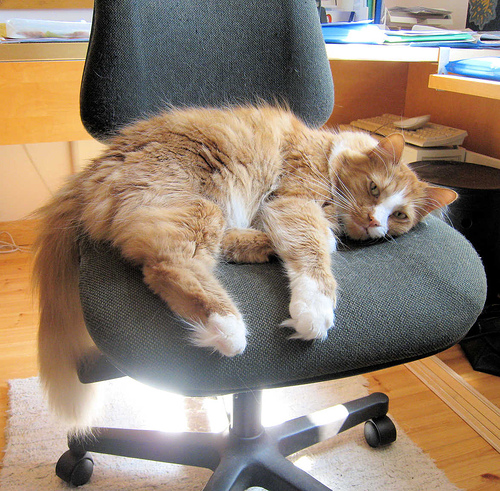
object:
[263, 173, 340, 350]
arm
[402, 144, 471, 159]
computer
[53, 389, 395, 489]
base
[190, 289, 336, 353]
paws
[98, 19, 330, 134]
fabric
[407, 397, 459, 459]
wood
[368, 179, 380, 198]
eye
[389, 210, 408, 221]
eye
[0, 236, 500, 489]
floor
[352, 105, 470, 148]
mouse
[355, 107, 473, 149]
white keyboard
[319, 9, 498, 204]
desk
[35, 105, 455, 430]
wing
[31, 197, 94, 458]
fluffy tail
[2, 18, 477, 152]
desk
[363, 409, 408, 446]
casters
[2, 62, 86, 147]
wall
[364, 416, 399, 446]
wheel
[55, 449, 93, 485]
wheel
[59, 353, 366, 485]
sunlight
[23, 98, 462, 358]
cat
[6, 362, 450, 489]
rug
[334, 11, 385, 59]
paper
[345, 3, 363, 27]
pen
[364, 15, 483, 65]
notebook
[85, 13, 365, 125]
backrest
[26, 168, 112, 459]
tail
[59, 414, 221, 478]
caster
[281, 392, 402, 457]
caster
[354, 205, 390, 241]
nose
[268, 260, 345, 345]
paw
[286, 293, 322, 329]
fur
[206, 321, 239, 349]
fur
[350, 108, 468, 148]
keyboard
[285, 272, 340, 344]
cat paws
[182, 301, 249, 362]
cat paws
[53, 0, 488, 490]
chair